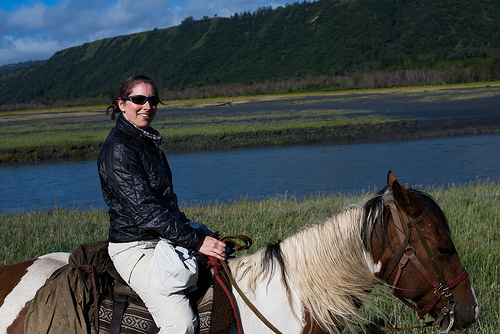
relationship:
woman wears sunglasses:
[92, 72, 232, 332] [122, 93, 156, 107]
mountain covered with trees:
[2, 2, 497, 111] [47, 15, 497, 76]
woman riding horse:
[92, 72, 234, 333] [0, 167, 479, 332]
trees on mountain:
[3, 0, 498, 105] [2, 0, 500, 111]